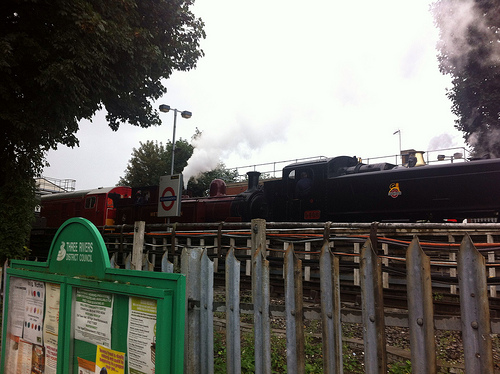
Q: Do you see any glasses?
A: No, there are no glasses.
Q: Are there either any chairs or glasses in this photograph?
A: No, there are no glasses or chairs.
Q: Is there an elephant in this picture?
A: No, there are no elephants.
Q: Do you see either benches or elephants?
A: No, there are no elephants or benches.